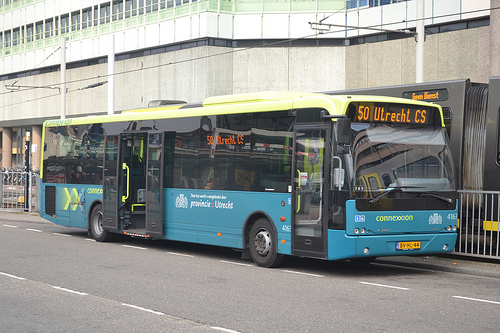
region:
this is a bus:
[38, 101, 474, 307]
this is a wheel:
[233, 185, 282, 278]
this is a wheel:
[76, 205, 111, 242]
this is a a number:
[349, 95, 374, 127]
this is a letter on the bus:
[372, 100, 384, 122]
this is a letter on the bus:
[196, 123, 225, 157]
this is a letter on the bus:
[384, 108, 401, 141]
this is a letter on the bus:
[393, 101, 409, 131]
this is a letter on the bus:
[408, 103, 426, 125]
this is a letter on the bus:
[204, 128, 226, 151]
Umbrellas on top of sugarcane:
[22, 94, 470, 269]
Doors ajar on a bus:
[103, 128, 171, 240]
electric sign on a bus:
[355, 98, 436, 130]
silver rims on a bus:
[251, 228, 275, 260]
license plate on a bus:
[396, 238, 426, 250]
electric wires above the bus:
[25, 38, 445, 93]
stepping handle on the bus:
[292, 164, 309, 220]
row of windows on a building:
[13, 0, 150, 45]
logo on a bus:
[169, 188, 193, 212]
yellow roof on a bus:
[197, 90, 344, 125]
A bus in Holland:
[21, 53, 479, 317]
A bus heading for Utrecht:
[26, 72, 481, 323]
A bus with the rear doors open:
[20, 81, 470, 331]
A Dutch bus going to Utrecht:
[17, 80, 484, 322]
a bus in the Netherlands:
[14, 73, 489, 313]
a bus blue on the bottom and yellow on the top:
[20, 73, 498, 277]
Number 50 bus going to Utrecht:
[30, 91, 470, 308]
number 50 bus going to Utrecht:
[24, 82, 466, 312]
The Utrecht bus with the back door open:
[28, 83, 493, 308]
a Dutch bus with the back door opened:
[14, 75, 496, 282]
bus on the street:
[31, 83, 463, 276]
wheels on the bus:
[70, 202, 305, 266]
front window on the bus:
[356, 130, 443, 192]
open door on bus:
[104, 130, 158, 237]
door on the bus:
[293, 123, 333, 253]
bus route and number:
[353, 102, 438, 127]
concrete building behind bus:
[1, 4, 483, 103]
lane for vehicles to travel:
[29, 238, 81, 273]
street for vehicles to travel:
[7, 229, 73, 329]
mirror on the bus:
[316, 118, 361, 151]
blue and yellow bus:
[35, 108, 450, 265]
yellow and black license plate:
[387, 237, 421, 256]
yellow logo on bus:
[368, 207, 413, 228]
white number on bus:
[441, 209, 457, 223]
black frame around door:
[276, 119, 336, 257]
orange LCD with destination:
[349, 104, 429, 125]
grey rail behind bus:
[451, 178, 498, 256]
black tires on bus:
[235, 227, 280, 259]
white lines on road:
[257, 263, 490, 318]